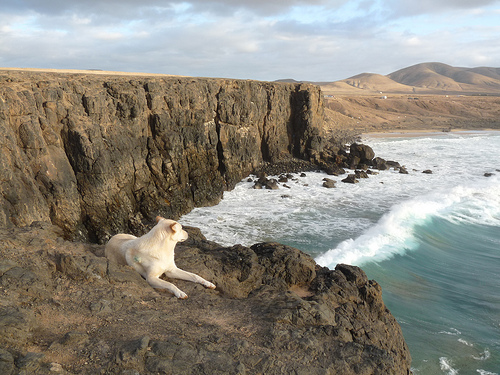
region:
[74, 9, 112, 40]
white clouds in blue sky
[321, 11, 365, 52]
white clouds in blue sky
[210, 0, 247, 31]
white clouds in blue sky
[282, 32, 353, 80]
white clouds in blue sky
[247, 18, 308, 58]
white clouds in blue sky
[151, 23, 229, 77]
white clouds in blue sky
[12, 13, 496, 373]
a scene outside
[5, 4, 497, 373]
a scene during the day time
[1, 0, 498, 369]
a photo of a ocean view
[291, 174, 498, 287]
a white wave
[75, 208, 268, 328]
a white dog looking at the ocean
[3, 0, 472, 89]
a sky with some clouds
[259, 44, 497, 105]
some hills in the background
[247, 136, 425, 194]
some rocks in the water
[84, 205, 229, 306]
a dog lying down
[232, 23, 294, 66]
white clouds in blue sky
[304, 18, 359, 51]
white clouds in blue sky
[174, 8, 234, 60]
white clouds in blue sky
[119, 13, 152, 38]
white clouds in blue sky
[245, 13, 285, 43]
white clouds in blue sky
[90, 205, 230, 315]
a dog is watching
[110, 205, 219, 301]
a dog is watching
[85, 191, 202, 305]
a dog is watching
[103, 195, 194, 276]
a dog is watching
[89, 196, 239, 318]
a dog is watching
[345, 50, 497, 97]
sand dunes in the distance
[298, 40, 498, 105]
sand dunes in the distance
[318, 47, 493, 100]
sand dunes in the distance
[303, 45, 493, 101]
sand dunes in the distance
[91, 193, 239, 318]
a dog sits on the rocks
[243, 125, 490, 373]
the ocean is off to the right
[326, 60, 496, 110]
some rolling hills are in the distance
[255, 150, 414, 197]
the water meets the rocks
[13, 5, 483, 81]
the clouds are in the sky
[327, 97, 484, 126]
land is in this region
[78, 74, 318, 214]
the cliffs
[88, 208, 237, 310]
the dog is golden yellow in color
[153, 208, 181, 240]
the dogs ears are set back